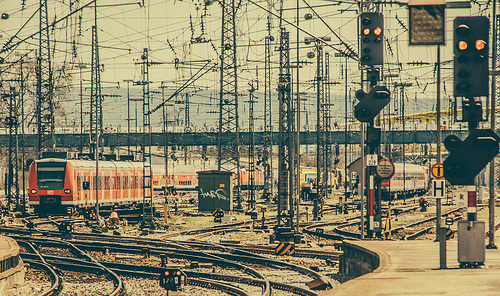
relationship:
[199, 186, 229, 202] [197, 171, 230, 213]
graffiti on building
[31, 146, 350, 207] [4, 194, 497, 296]
train on tracks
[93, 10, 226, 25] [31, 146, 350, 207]
line above train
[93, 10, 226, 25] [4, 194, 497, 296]
line above tracks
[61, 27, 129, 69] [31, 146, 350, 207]
line above train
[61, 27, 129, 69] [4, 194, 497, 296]
line above tracks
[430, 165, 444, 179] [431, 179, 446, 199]
sign above sign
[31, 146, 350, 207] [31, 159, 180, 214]
train has engine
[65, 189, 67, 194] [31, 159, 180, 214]
light on engine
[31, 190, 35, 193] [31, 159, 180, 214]
light on engine